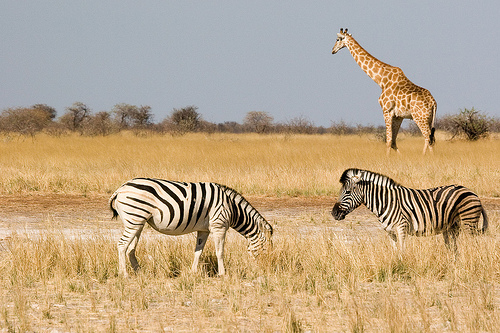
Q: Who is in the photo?
A: Nobody.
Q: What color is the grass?
A: Brown.